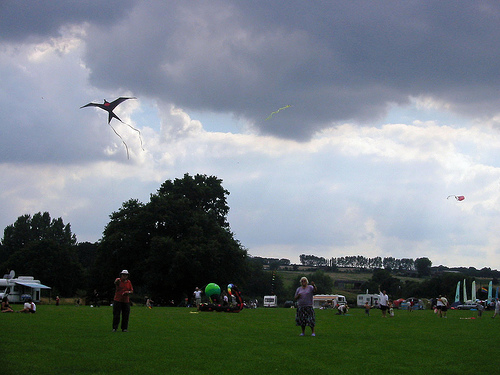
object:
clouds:
[1, 0, 499, 133]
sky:
[5, 11, 495, 263]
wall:
[453, 276, 493, 305]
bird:
[80, 90, 130, 122]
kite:
[69, 85, 167, 171]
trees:
[102, 175, 248, 300]